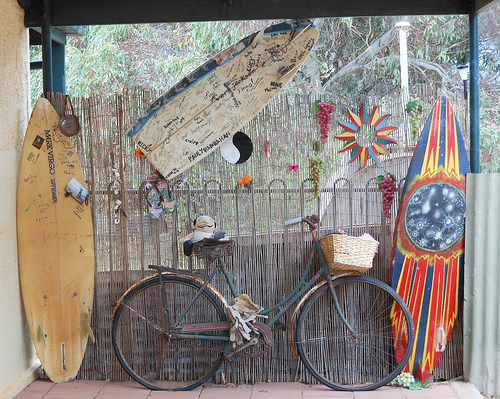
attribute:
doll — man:
[183, 211, 230, 256]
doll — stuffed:
[174, 214, 230, 259]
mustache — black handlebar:
[194, 221, 215, 231]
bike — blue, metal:
[114, 205, 413, 357]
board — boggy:
[393, 99, 465, 384]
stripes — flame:
[394, 101, 462, 383]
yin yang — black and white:
[216, 127, 253, 167]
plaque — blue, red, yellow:
[334, 98, 411, 176]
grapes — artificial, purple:
[375, 173, 395, 220]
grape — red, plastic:
[310, 100, 343, 142]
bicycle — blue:
[107, 215, 417, 397]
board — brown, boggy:
[16, 94, 96, 384]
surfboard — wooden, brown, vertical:
[23, 110, 102, 350]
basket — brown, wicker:
[319, 230, 379, 272]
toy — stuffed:
[169, 211, 236, 242]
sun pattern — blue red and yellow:
[338, 97, 398, 167]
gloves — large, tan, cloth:
[226, 293, 266, 351]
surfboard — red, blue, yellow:
[385, 82, 485, 377]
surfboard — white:
[128, 16, 318, 181]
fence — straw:
[136, 99, 477, 387]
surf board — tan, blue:
[126, 21, 320, 179]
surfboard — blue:
[392, 91, 472, 385]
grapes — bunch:
[311, 88, 359, 161]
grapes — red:
[317, 99, 332, 147]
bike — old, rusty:
[107, 207, 419, 394]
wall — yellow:
[7, 17, 27, 397]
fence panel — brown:
[33, 86, 468, 383]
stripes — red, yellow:
[392, 252, 460, 377]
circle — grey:
[403, 182, 466, 250]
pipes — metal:
[112, 178, 387, 382]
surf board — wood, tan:
[11, 90, 99, 388]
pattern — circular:
[402, 168, 466, 258]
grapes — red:
[309, 93, 345, 143]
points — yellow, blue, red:
[335, 105, 397, 165]